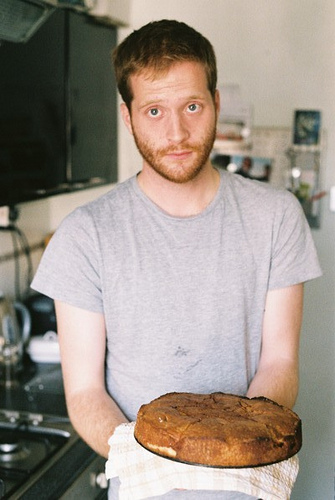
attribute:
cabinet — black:
[1, 1, 120, 205]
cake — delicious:
[144, 386, 307, 476]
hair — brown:
[101, 16, 222, 98]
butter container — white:
[24, 333, 66, 367]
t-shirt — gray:
[29, 169, 321, 498]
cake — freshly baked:
[134, 392, 301, 465]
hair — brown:
[97, 15, 225, 107]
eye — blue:
[185, 102, 204, 113]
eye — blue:
[144, 104, 164, 118]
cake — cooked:
[126, 385, 311, 473]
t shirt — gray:
[30, 162, 324, 431]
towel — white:
[79, 388, 326, 490]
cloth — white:
[104, 419, 299, 497]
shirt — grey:
[29, 166, 322, 422]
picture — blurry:
[291, 105, 324, 146]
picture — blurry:
[224, 150, 277, 182]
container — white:
[24, 329, 62, 362]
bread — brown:
[142, 372, 333, 492]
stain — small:
[172, 347, 190, 370]